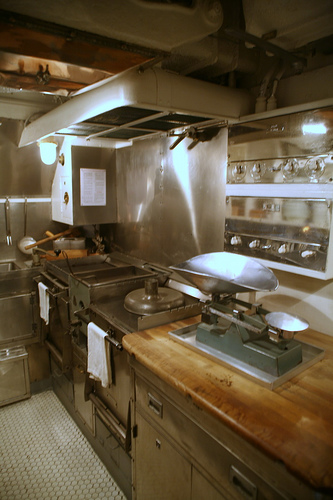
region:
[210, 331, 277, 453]
the counter top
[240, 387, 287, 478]
the counter top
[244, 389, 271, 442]
the counter top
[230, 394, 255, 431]
the counter top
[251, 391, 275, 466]
the counter top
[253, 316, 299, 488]
the counter top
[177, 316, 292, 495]
the counter top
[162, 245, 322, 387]
baby scales set up on a kitchen counter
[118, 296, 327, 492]
wooden kitchen counter top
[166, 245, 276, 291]
scale bed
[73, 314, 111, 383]
towel hanging off of the kitchen stove on the left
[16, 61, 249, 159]
kitchen range hood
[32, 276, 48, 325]
towel hanging on the kitchen stove on the left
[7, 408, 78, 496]
dirty kitchen floor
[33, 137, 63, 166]
light bulb hanging from the range hood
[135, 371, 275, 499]
drawer in the kitchen cabinet where the scale sets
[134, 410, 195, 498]
door to the kitchen cabinet where the baby scale sets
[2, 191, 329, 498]
a kitchen with a wood counter aand scale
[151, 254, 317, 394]
a scale on top of counter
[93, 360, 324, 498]
a wooden old cabinet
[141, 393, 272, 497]
two metal handles to open cabinet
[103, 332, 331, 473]
light brown wooden cutting board cabinet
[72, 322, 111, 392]
a white dish towel hanging from rack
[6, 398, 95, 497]
white tile floor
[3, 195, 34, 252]
utensils hanging from back wall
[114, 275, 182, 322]
silver lid to a cooking pan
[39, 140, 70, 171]
glass light fixture and bulb is on hanging from wall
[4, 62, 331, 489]
industrial grade kitchen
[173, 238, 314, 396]
silver food scale on counter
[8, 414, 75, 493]
white tile kitchen floor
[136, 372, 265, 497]
stainless steel drawer and cabinet door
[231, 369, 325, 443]
light wood counter top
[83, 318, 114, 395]
white tea towel folded over bar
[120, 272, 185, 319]
round pot or pan lid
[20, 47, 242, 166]
exhaust fan hood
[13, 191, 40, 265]
large food service ladel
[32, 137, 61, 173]
glass light fixture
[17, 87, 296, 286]
a restuarant kitchen area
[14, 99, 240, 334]
the kitchen is cluttered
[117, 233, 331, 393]
the kitchen looks clean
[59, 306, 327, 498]
the appliances are ready for use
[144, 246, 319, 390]
this is a kitchen scale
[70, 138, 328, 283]
the stove has a metal back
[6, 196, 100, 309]
a lot of utensils on the counter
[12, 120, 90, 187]
a light in kitchen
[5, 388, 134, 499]
the floor is dirty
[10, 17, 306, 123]
exhaust hood above the stove